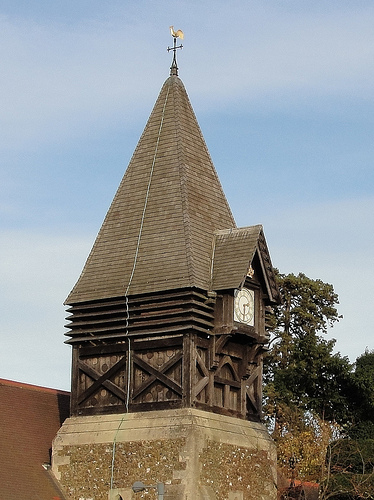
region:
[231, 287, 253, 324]
White clock face on the tower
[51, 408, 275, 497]
Cement base of the tower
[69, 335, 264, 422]
Wooden walls on the cement base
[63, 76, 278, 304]
Tall spire of the clock tower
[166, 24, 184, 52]
Weather cock at the top of the spire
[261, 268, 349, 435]
A tall tree3 behind the tower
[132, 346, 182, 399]
Wooden crossbars supporting the wall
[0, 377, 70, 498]
Tiled roof of an attached structure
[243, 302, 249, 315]
Two hands of the clock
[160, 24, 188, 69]
Wind chime on top of tower.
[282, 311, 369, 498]
Trees growing in the background.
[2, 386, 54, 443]
Shingles on teh roof.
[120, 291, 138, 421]
Wire going up the building.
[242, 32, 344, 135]
Clouds in the sky.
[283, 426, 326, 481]
Yellow leaves on the tree.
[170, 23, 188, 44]
Rooster on wind chime.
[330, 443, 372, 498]
Empty branches beside trees.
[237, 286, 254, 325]
white clock on tower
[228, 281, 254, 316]
roman numerals on clock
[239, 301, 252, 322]
gold colored arms of clock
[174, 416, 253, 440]
bricks in stone base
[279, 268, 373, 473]
tall trees growing on right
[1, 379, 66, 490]
red roof of building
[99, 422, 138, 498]
line running down side of building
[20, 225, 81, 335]
white clouds in sky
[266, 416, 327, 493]
light bushes growing near tower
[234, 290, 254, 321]
clock face on right of building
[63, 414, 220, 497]
stone base of clock tower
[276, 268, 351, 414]
trees growing around tower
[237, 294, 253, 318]
roman numerals on clock face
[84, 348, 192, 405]
wooden wall of tower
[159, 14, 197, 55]
metal rooster on top of tower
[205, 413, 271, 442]
bricks on side of base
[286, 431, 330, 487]
light bushes by base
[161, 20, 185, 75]
A weathervane in the sky.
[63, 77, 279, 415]
A clock on a tower.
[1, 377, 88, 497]
Brown shingles on a roof.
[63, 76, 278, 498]
A cable on the side of a building.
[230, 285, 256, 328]
A white round clock.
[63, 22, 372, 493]
Trees beside a building.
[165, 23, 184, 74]
Rooster on a weather vane.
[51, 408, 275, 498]
A building constructed of stone.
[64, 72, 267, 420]
A tower constructed of wood.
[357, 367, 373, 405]
green leaves on the tree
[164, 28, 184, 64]
a weather vane is above the roof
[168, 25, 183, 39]
the metal rooster is gold in color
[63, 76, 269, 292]
the roof is made of tiles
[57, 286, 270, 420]
the spire is made of wood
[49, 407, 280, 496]
the base of the spire is made of concrete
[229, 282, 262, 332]
a clock is on the tower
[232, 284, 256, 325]
the clock has a white clockface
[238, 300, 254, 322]
the dials are made of metal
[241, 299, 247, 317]
the dials are gold in color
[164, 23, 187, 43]
rooster on top of tower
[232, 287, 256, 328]
square white clock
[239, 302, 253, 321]
black clock hands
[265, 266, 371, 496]
green tree leaves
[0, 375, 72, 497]
red bricked roof of house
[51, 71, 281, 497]
bricked tower on red roof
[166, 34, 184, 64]
metal cross on top of tower